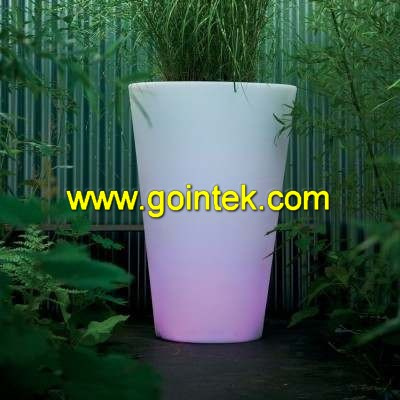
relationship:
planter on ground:
[126, 79, 299, 347] [63, 321, 397, 399]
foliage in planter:
[83, 2, 289, 81] [126, 79, 299, 347]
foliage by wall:
[83, 2, 289, 81] [1, 2, 399, 314]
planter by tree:
[126, 79, 299, 347] [274, 0, 398, 230]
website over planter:
[66, 183, 330, 219] [126, 79, 299, 347]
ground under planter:
[63, 321, 397, 399] [126, 79, 299, 347]